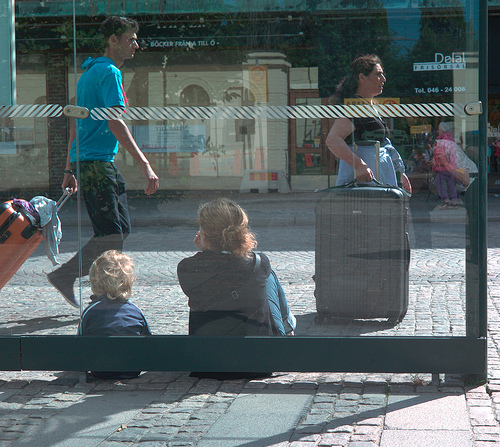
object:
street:
[0, 220, 500, 447]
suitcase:
[315, 183, 411, 324]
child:
[74, 247, 148, 376]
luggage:
[0, 198, 40, 289]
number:
[428, 87, 465, 94]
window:
[316, 17, 466, 98]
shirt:
[69, 59, 128, 166]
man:
[51, 10, 160, 304]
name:
[434, 52, 466, 63]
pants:
[42, 162, 132, 307]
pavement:
[0, 186, 500, 244]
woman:
[179, 197, 300, 338]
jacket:
[177, 250, 273, 380]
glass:
[0, 3, 482, 335]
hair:
[197, 198, 254, 254]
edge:
[459, 393, 485, 408]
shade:
[131, 4, 224, 194]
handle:
[55, 194, 70, 210]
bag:
[433, 141, 479, 194]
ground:
[0, 210, 498, 447]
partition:
[208, 0, 308, 37]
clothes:
[12, 199, 43, 224]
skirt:
[338, 144, 400, 189]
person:
[408, 141, 431, 249]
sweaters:
[30, 197, 66, 267]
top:
[346, 117, 391, 145]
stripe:
[0, 101, 472, 119]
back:
[346, 137, 353, 145]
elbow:
[325, 135, 333, 148]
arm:
[326, 119, 366, 168]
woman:
[324, 54, 411, 201]